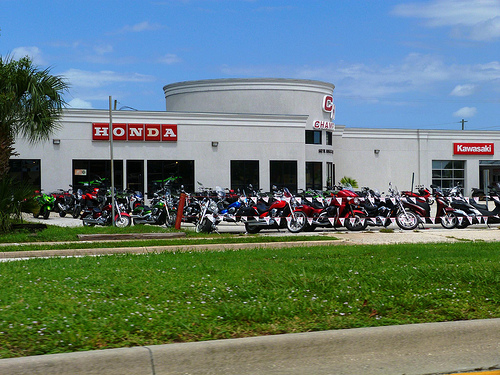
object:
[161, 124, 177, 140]
tile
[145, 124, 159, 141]
tile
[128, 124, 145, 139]
tile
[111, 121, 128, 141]
tile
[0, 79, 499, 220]
building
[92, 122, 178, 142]
honda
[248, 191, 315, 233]
bike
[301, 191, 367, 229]
bike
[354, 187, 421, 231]
bike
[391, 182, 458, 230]
bike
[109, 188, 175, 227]
bike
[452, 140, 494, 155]
kawasaki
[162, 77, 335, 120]
middle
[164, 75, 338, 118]
circular shape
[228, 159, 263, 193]
window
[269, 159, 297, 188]
window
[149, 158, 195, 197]
window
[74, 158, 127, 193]
window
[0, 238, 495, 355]
grass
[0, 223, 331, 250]
grass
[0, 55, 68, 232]
tree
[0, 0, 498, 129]
sky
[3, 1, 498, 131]
background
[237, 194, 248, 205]
banner flag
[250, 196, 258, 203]
banner flag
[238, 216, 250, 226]
banner flag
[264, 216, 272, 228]
banner flag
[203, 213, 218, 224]
banner flag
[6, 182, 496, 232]
lot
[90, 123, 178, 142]
sign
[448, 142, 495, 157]
sign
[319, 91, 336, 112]
sign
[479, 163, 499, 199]
garage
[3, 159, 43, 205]
garage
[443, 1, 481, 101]
clouds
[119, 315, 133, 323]
flowers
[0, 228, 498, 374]
street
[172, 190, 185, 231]
pole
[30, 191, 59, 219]
bike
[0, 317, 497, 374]
cement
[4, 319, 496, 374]
curb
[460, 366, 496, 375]
line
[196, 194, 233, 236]
bike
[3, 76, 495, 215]
dealership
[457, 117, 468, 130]
pole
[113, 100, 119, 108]
pole